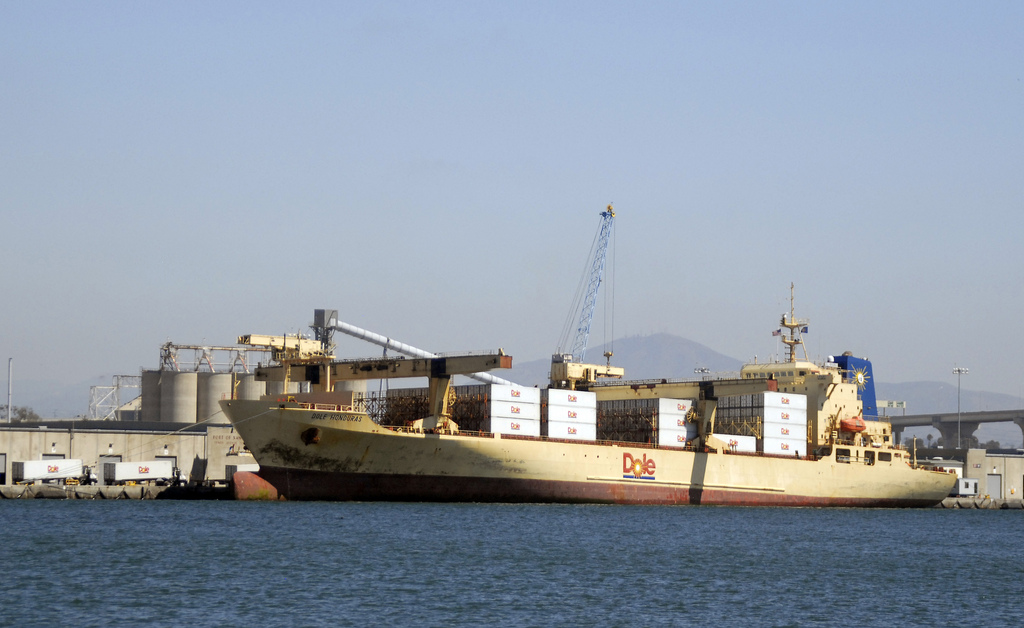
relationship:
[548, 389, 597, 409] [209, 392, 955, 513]
container on a ship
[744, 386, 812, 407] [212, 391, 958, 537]
container on a ship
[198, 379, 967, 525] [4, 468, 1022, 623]
boat on water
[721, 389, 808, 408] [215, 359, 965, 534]
container on boat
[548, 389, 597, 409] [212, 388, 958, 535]
container on boat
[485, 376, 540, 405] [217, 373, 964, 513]
container on boat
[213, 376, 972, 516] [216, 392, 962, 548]
container on boat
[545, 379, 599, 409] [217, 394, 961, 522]
container on boat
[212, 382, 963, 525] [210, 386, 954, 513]
container on boat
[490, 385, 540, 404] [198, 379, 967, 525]
container on boat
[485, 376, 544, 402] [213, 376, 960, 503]
container on boat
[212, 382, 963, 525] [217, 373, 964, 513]
container on boat